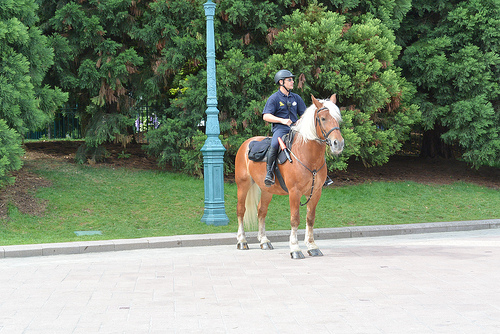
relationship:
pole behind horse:
[199, 1, 231, 232] [233, 90, 346, 263]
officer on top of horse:
[262, 68, 309, 188] [233, 90, 346, 263]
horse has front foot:
[233, 90, 346, 263] [287, 242, 308, 264]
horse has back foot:
[233, 90, 346, 263] [235, 233, 252, 253]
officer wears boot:
[262, 68, 309, 188] [261, 159, 278, 187]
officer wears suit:
[262, 68, 309, 188] [261, 91, 308, 131]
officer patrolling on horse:
[262, 68, 309, 188] [233, 90, 346, 263]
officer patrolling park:
[262, 68, 309, 188] [1, 1, 499, 333]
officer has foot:
[262, 68, 309, 188] [262, 169, 277, 186]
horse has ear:
[233, 90, 346, 263] [309, 94, 325, 111]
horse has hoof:
[233, 90, 346, 263] [306, 247, 327, 258]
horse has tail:
[233, 90, 346, 263] [245, 183, 262, 233]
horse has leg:
[233, 90, 346, 263] [284, 181, 309, 264]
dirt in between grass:
[0, 143, 63, 232] [1, 154, 497, 244]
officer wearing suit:
[262, 68, 309, 188] [261, 91, 308, 150]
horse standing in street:
[233, 90, 346, 263] [2, 227, 498, 332]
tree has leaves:
[39, 0, 179, 165] [115, 47, 147, 77]